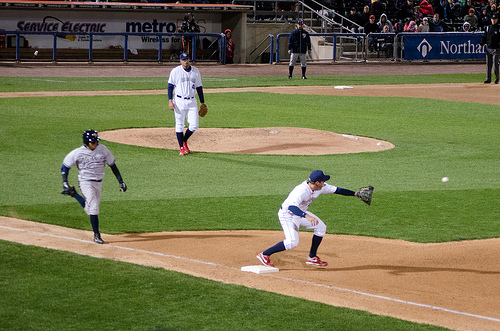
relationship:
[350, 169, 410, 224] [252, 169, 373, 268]
glove of man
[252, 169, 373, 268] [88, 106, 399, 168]
man standing on pitcher's mound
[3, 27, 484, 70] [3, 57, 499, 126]
fence at edge of field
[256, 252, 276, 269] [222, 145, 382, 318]
foot of player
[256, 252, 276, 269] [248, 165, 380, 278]
foot of ball player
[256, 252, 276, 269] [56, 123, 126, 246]
foot of ball player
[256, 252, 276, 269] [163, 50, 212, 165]
foot of ball player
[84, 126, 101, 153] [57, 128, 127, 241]
head of player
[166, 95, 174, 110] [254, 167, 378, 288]
hand of ball player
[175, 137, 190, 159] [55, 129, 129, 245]
feet of head man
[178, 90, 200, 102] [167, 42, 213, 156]
belt of player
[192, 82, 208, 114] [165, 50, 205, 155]
arm of man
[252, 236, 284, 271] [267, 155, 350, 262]
foot of man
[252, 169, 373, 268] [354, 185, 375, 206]
man wearing glove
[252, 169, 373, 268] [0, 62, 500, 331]
man in field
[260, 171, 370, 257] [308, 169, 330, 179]
man wearing hat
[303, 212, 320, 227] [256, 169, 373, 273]
hand of player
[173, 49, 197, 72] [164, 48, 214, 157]
head of player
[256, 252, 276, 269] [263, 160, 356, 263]
foot of player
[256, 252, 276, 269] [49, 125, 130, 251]
foot of player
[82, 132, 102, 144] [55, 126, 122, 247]
head of man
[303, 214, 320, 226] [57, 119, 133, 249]
hand of man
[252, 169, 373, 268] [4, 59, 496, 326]
man on a field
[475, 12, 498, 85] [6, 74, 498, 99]
umpire standing on base line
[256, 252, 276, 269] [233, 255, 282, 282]
foot on base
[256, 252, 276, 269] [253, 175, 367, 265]
foot of baseball player